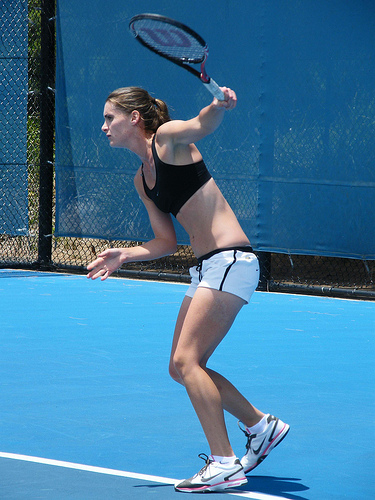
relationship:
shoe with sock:
[172, 455, 248, 495] [208, 449, 237, 466]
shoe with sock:
[238, 414, 293, 475] [247, 411, 266, 436]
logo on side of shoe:
[197, 471, 222, 483] [171, 459, 250, 494]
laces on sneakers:
[191, 451, 213, 478] [171, 458, 252, 497]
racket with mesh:
[127, 12, 225, 103] [133, 19, 203, 61]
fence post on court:
[35, 1, 57, 267] [0, 270, 375, 500]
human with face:
[83, 85, 289, 496] [99, 107, 121, 148]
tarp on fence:
[213, 74, 370, 245] [4, 8, 361, 295]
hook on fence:
[25, 83, 53, 96] [0, 42, 364, 296]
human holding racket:
[83, 85, 289, 496] [127, 12, 225, 103]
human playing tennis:
[83, 85, 289, 496] [3, 8, 363, 490]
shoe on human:
[172, 455, 248, 496] [83, 85, 289, 496]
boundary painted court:
[0, 448, 287, 500] [2, 270, 361, 488]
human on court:
[83, 85, 289, 496] [2, 270, 361, 488]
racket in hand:
[121, 6, 242, 108] [212, 81, 240, 110]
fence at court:
[4, 8, 361, 295] [2, 270, 361, 488]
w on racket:
[146, 27, 191, 52] [129, 9, 245, 115]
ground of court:
[3, 269, 346, 498] [4, 6, 359, 490]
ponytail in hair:
[148, 94, 171, 120] [110, 80, 182, 125]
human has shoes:
[83, 85, 289, 496] [174, 412, 288, 494]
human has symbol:
[83, 85, 289, 496] [217, 455, 230, 464]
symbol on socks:
[217, 455, 230, 464] [202, 414, 272, 461]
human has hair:
[83, 85, 289, 496] [106, 81, 172, 125]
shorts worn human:
[178, 244, 265, 304] [82, 12, 302, 491]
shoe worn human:
[172, 455, 248, 496] [82, 12, 302, 491]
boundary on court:
[3, 448, 255, 498] [2, 270, 361, 488]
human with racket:
[77, 67, 307, 436] [127, 12, 225, 103]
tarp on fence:
[213, 74, 370, 245] [14, 12, 372, 315]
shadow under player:
[204, 464, 294, 498] [89, 74, 313, 420]